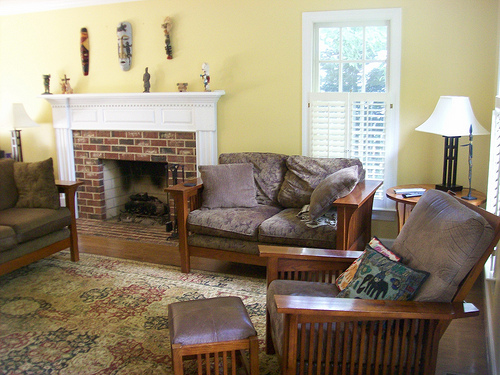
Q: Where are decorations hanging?
A: Over fireplace.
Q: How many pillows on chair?
A: Two.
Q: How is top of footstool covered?
A: Leather.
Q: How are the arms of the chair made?
A: With wood.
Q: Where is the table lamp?
A: Right corner of room.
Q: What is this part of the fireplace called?
A: Mantle.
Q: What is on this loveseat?
A: Pillows.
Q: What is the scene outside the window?
A: Trees.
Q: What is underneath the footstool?
A: Rug.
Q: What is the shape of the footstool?
A: Square.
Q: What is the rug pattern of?
A: Flowers.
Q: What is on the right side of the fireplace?
A: Fireplace tools.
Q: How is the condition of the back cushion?
A: Wrinkled.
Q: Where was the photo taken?
A: Living room.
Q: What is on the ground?
A: Rug.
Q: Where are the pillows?
A: On chairs.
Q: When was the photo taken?
A: In the daytime.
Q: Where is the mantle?
A: Above fireplace.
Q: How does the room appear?
A: Clean.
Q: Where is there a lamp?
A: Side table.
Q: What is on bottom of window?
A: Blinds.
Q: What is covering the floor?
A: The large rug.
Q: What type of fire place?
A: A brick fireplace.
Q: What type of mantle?
A: A white mantle.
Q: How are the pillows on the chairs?
A: Two are on the chair.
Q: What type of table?
A: A wood table.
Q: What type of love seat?
A: A wooden love seat.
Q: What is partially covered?
A: The window is covered.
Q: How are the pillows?
A: Two are on the couch.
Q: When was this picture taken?
A: Daytime.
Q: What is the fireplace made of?
A: Brick.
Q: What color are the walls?
A: Yellow.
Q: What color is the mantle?
A: White.